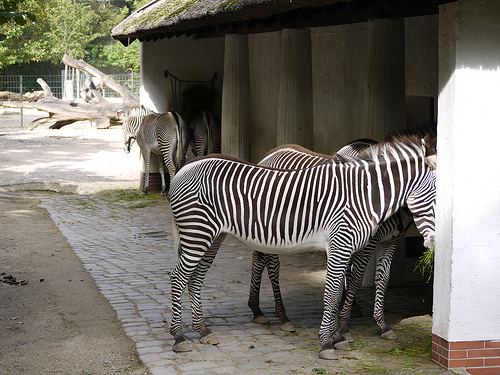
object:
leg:
[318, 245, 351, 358]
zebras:
[155, 129, 436, 336]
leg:
[372, 239, 406, 352]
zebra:
[252, 172, 400, 315]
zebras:
[162, 130, 437, 357]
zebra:
[95, 92, 192, 191]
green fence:
[1, 71, 144, 129]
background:
[2, 0, 143, 190]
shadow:
[419, 52, 491, 139]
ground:
[6, 190, 211, 346]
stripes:
[171, 133, 422, 344]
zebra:
[121, 104, 185, 208]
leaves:
[8, 0, 108, 62]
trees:
[0, 0, 138, 74]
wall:
[444, 119, 487, 260]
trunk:
[5, 95, 131, 136]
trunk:
[14, 72, 150, 123]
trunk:
[56, 49, 142, 119]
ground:
[4, 99, 472, 371]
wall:
[451, 127, 487, 257]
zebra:
[89, 83, 188, 208]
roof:
[100, 4, 493, 45]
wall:
[461, 47, 498, 286]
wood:
[24, 79, 134, 133]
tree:
[18, 10, 111, 67]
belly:
[239, 236, 322, 257]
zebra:
[130, 140, 458, 362]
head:
[410, 142, 447, 249]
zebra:
[187, 110, 227, 163]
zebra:
[155, 110, 186, 174]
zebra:
[158, 127, 437, 362]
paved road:
[1, 192, 134, 372]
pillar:
[434, 2, 499, 371]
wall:
[428, 332, 498, 374]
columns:
[213, 14, 410, 163]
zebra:
[230, 136, 437, 342]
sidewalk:
[0, 96, 168, 369]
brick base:
[425, 331, 482, 367]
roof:
[110, 1, 392, 39]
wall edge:
[423, 4, 470, 348]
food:
[419, 237, 439, 284]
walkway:
[59, 189, 279, 372]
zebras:
[124, 108, 436, 362]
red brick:
[427, 333, 484, 369]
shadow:
[176, 98, 219, 154]